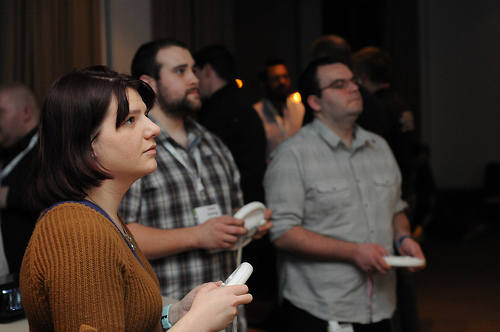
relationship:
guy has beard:
[116, 39, 274, 332] [157, 86, 202, 116]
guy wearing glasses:
[262, 58, 427, 332] [318, 72, 364, 89]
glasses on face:
[318, 72, 364, 89] [313, 60, 365, 117]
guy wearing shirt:
[262, 58, 427, 332] [263, 115, 408, 322]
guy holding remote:
[116, 39, 274, 332] [227, 200, 268, 251]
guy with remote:
[262, 58, 427, 332] [227, 200, 268, 251]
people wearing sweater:
[18, 65, 254, 332] [5, 188, 166, 330]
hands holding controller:
[178, 277, 256, 330] [219, 262, 254, 289]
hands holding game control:
[184, 202, 279, 256] [227, 201, 268, 252]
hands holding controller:
[338, 226, 429, 276] [377, 254, 426, 268]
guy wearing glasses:
[262, 58, 427, 332] [314, 74, 356, 91]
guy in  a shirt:
[116, 39, 274, 332] [118, 107, 258, 329]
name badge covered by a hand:
[185, 196, 233, 226] [181, 210, 251, 259]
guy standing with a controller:
[262, 58, 427, 332] [377, 254, 426, 268]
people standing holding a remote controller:
[18, 65, 254, 332] [221, 260, 253, 282]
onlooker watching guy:
[249, 61, 304, 146] [262, 58, 427, 332]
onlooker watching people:
[249, 61, 304, 146] [25, 60, 166, 330]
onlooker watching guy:
[249, 61, 304, 146] [116, 39, 274, 332]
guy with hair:
[116, 39, 274, 332] [110, 32, 190, 102]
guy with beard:
[116, 39, 274, 332] [149, 81, 208, 118]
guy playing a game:
[116, 39, 274, 332] [176, 138, 499, 332]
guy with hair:
[262, 58, 427, 332] [300, 55, 347, 102]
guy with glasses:
[262, 58, 427, 332] [312, 69, 367, 99]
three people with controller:
[18, 37, 425, 329] [219, 262, 254, 289]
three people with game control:
[18, 37, 425, 329] [222, 191, 273, 254]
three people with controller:
[18, 37, 425, 329] [377, 254, 426, 268]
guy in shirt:
[116, 39, 274, 332] [118, 107, 258, 329]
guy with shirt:
[262, 58, 427, 332] [263, 115, 408, 322]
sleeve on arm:
[250, 154, 322, 298] [267, 150, 381, 278]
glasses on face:
[321, 77, 357, 91] [305, 64, 383, 148]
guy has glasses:
[262, 58, 427, 332] [322, 75, 364, 90]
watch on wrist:
[158, 297, 175, 329] [190, 213, 208, 251]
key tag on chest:
[197, 203, 219, 217] [174, 127, 193, 148]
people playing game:
[43, 68, 395, 325] [477, 34, 499, 138]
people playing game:
[18, 65, 254, 332] [477, 34, 499, 138]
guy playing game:
[262, 58, 427, 332] [477, 34, 499, 138]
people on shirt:
[18, 65, 254, 332] [20, 197, 169, 329]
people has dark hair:
[18, 65, 254, 332] [47, 70, 153, 175]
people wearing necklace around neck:
[18, 65, 254, 332] [79, 177, 139, 214]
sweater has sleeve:
[34, 201, 152, 329] [39, 206, 129, 330]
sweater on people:
[19, 201, 164, 332] [18, 65, 254, 332]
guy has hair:
[262, 58, 427, 332] [129, 38, 169, 88]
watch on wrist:
[391, 227, 414, 248] [389, 210, 411, 229]